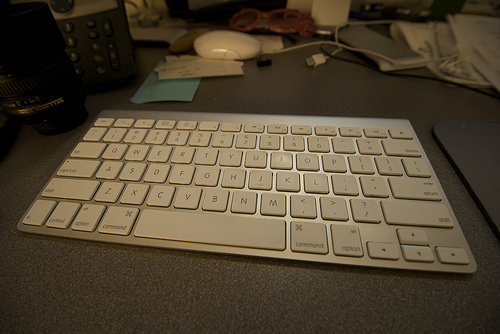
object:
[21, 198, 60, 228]
keys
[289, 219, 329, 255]
button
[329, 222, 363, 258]
button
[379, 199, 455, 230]
shift key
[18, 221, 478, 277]
edge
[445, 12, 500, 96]
papers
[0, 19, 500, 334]
desk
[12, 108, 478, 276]
keyboard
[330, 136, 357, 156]
keys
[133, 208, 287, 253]
white keyboard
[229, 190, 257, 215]
keyboard button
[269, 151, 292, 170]
i key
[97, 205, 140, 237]
keyboard button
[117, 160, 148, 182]
button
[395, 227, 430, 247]
keys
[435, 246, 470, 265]
keys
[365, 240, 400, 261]
arrow keys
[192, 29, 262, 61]
mouse